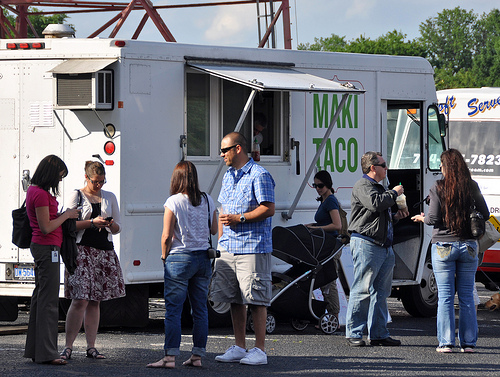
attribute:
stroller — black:
[253, 215, 359, 338]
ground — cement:
[0, 326, 497, 375]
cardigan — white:
[66, 162, 123, 243]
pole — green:
[91, 6, 186, 48]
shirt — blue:
[209, 158, 277, 252]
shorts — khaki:
[209, 247, 276, 307]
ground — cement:
[286, 340, 357, 372]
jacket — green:
[342, 233, 397, 342]